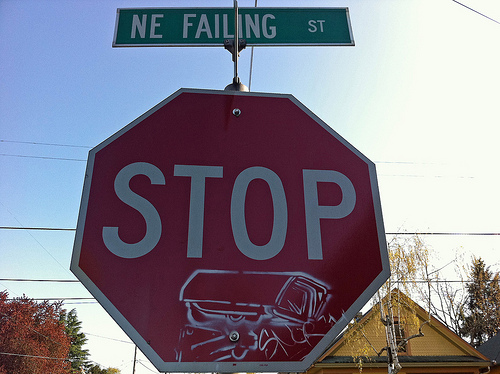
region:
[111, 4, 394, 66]
name on the board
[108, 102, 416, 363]
a big traffic signal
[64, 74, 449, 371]
a board with traffic signal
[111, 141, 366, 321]
a text written in board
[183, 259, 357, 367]
a small design in board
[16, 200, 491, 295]
a thin electric wires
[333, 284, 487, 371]
a part of the home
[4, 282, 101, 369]
a beautiful view of trees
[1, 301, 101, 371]
a beautiful red leafs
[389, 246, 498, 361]
clear view of trees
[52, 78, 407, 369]
big red stop sign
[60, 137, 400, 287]
red stop sign with the letter s on it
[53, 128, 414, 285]
red stop sign with the letter t on it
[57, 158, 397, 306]
red stop sign with the letter o on it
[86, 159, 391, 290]
red stop sign with the letter p on it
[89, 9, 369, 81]
street sign with the letter n on it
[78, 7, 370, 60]
street sign with the letter e on it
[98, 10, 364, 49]
street sign with the letter f on it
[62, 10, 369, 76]
street sign with the letter i n on it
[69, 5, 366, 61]
street sign with the letter l on it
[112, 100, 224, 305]
a stop sign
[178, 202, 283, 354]
a stop sign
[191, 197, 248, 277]
a stop sign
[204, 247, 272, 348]
a stop sign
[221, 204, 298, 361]
a stop sign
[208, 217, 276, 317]
a stop sign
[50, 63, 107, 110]
blue color in the sky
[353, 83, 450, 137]
sunlight shining in the sky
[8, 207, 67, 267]
over head electrical wires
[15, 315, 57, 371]
tree with gold leaves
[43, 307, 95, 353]
green tree behind the gold leaves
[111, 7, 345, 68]
green and white street sign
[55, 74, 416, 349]
red sign with white words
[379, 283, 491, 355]
triangle roof on yellow building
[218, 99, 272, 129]
small screw in sign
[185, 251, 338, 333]
grafitti on red sign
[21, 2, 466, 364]
Close up picture of a stop sign.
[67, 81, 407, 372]
Sign with white border.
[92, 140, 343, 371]
Graffiti on a stop sign.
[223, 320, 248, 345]
Silver bolt on bottom of sign.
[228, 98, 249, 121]
Silver bolt on top of sign.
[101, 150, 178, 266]
The letter S in white.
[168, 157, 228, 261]
The letter T in white.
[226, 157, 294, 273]
The letter O in white.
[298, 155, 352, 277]
The letter P in white.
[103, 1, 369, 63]
A green and white street sign.